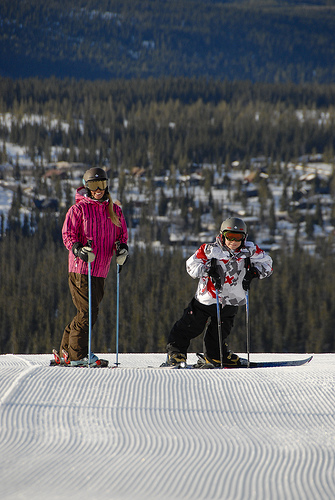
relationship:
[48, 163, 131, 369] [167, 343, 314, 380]
mom on skis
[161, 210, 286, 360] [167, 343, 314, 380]
boy on skis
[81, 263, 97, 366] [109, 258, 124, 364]
blue metal pole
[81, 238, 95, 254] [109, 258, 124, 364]
metal blue pole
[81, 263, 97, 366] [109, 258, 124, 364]
blue ski pole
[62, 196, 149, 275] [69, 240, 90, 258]
jacket pink black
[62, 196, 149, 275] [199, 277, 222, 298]
jacket with red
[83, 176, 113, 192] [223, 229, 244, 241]
goggles a pair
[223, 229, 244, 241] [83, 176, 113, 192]
pair of goggles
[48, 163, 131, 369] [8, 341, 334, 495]
mom on slopes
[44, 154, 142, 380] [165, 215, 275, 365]
mom and boy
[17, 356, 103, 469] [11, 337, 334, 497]
lines in snow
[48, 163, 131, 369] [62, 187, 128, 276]
mom wearing jacket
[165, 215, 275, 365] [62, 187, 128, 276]
boy wearing jacket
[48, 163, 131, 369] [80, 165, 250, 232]
mom wearing helmets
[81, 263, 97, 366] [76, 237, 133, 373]
blue ski poles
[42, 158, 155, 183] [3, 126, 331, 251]
houses in ground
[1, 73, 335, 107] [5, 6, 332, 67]
trees on horizon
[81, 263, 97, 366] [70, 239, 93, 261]
blue red binding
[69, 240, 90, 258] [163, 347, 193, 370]
black yellow boot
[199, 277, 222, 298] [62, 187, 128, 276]
red white jacket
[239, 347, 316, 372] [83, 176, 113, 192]
ski orange goggles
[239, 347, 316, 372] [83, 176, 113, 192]
ski pair goggles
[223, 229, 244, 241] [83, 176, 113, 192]
pair ski goggles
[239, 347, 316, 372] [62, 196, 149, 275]
ski pink jacket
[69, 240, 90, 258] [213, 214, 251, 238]
black a helmet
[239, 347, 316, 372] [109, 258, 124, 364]
ski a pole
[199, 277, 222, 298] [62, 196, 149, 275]
red ski jacket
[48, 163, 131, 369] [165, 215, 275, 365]
mom and boy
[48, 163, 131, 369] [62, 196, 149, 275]
mom wears jacket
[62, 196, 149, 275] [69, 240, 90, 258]
jacket has black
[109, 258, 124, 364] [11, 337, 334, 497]
pole on snow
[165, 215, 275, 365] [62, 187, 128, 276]
boy wears jacket